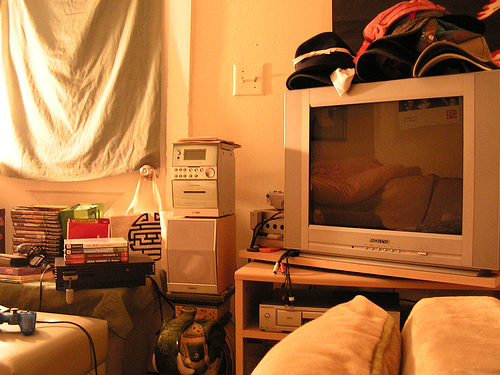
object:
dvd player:
[255, 288, 401, 335]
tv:
[283, 68, 499, 275]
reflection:
[302, 97, 462, 231]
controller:
[1, 306, 37, 336]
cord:
[34, 316, 100, 375]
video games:
[12, 205, 59, 215]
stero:
[171, 143, 237, 217]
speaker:
[169, 220, 236, 293]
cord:
[271, 247, 299, 309]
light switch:
[231, 64, 264, 95]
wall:
[163, 0, 285, 217]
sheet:
[1, 1, 161, 182]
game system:
[54, 259, 151, 291]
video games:
[62, 237, 128, 249]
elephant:
[153, 289, 232, 374]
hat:
[286, 33, 358, 92]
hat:
[351, 1, 443, 64]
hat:
[353, 44, 411, 83]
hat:
[408, 31, 493, 79]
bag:
[106, 177, 171, 267]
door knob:
[140, 163, 154, 180]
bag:
[61, 202, 103, 239]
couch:
[241, 293, 499, 375]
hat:
[382, 8, 440, 37]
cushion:
[250, 294, 403, 375]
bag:
[67, 218, 109, 241]